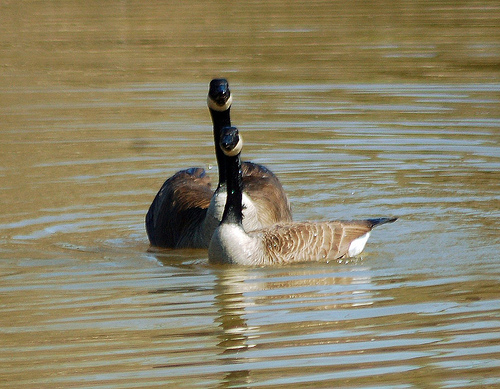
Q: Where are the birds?
A: In water.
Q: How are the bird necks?
A: Long.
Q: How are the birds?
A: Feathered.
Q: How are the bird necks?
A: Lean.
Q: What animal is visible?
A: Bird.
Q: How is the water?
A: Calm.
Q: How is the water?
A: Rippled.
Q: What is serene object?
A: Water.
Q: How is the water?
A: Wavy.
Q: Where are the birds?
A: In the water.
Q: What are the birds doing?
A: Swimming.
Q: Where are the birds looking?
A: At the camera.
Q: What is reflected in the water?
A: The sky.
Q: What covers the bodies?
A: Feathers.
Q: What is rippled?
A: Water.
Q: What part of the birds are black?
A: Necks.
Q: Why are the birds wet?
A: They are in the water.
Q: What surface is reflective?
A: Water.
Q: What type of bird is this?
A: Geese.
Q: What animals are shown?
A: Geese.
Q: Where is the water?
A: Under the geese.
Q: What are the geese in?
A: Water.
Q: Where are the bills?
A: On the geese.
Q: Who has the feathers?
A: The geese.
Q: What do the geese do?
A: Paddle.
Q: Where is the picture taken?
A: A river.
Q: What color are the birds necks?
A: Black.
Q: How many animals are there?
A: Two.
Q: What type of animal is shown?
A: Goose.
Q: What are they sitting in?
A: Water.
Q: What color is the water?
A: Green.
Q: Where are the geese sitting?
A: Pond.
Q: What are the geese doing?
A: Floating.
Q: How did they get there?
A: Flew.